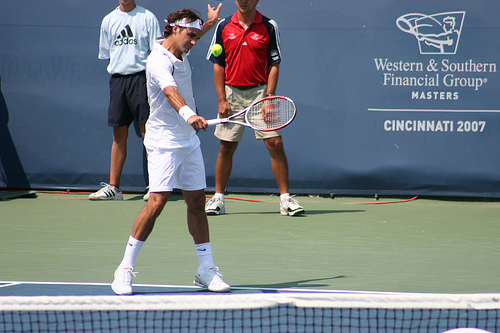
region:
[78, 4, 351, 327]
a tennis player serving the ball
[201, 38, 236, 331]
a tennis ball in mid air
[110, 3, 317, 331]
a tennis player in a white outfit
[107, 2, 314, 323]
a tennis player with a white headband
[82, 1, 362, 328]
a male tennis player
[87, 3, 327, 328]
a male tennis player serving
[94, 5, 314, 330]
a male tennis player dressed in white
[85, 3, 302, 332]
a professional tennis player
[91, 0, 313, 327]
a tennis pro serving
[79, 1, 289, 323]
a tennis player serving the ball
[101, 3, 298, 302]
The man is holding a tennis racket.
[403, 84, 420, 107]
The letter is white.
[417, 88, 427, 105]
The letter is white.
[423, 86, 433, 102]
The letter is white.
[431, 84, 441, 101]
The letter is white.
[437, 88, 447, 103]
The letter is white.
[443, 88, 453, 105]
The letter is white.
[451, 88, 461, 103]
The letter is white.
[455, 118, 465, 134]
The number is white.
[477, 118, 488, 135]
The number is white.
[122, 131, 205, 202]
Federer has white shorts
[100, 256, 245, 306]
white shoes are tied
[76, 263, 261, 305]
white line on court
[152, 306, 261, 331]
court is dark blue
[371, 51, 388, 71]
The letter is white.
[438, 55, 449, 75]
The letter is white.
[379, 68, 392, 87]
The letter is white.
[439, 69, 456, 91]
The letter is white.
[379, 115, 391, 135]
The letter is white.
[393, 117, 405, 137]
The letter is white.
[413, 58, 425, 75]
The letter is white.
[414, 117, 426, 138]
The letter is white.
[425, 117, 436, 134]
The letter is white.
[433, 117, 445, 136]
The letter is white.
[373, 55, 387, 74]
white letter on wall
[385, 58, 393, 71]
white letter on wall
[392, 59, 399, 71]
white letter on wall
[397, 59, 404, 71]
white letter on wall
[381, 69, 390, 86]
white letter on wall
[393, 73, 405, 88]
white letter on wall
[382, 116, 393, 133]
white letter on wall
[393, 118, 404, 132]
white letter on wall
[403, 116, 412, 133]
white letter on wall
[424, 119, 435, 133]
white letter on wall